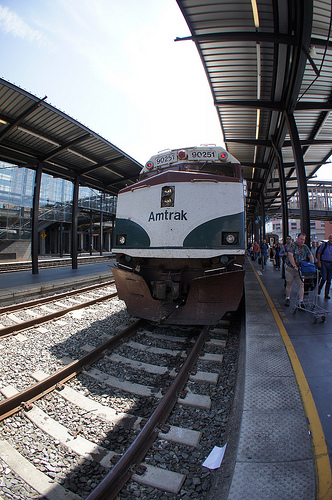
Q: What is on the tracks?
A: A train.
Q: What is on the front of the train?
A: Headlights.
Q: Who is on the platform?
A: Some people.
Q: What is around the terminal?
A: Buildings.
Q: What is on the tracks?
A: Train.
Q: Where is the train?
A: At the station.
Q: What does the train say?
A: Amtrak.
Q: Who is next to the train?
A: Some people.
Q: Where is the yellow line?
A: On the cement.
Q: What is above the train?
A: The sky.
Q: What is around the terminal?
A: Buildigns.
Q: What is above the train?
A: Overhang.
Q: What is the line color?
A: Yellow.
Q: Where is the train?
A: Tracks.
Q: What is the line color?
A: Yellow.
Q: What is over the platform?
A: Shelter.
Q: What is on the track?
A: Trains.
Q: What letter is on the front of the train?
A: Amtrak.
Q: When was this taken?
A: During the day.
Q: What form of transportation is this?
A: Train.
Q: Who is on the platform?
A: Passengers.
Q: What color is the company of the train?
A: Green.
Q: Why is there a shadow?
A: It's a sunny day.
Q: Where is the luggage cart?
A: On the platform.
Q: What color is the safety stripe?
A: Yellow.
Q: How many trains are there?
A: One.